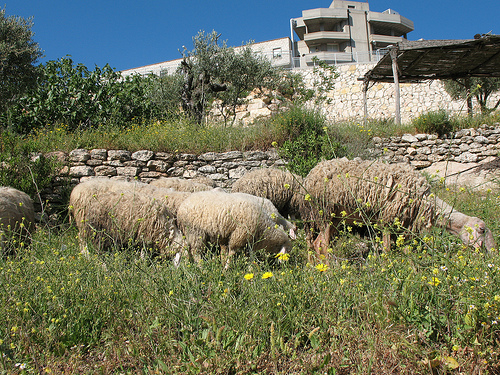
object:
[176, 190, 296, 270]
sheep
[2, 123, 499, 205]
wall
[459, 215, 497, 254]
head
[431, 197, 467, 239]
neck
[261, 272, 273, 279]
flowers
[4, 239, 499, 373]
grass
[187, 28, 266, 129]
trees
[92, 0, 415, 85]
building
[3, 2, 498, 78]
sky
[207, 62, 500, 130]
wall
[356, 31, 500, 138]
fence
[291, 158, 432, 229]
wool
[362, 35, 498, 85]
roof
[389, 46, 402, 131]
supports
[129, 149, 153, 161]
rocks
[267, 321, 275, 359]
plants